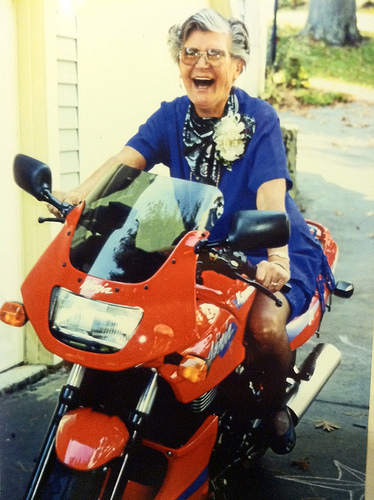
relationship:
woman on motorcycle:
[45, 9, 333, 455] [1, 153, 344, 498]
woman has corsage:
[45, 9, 333, 455] [212, 107, 248, 164]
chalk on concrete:
[275, 456, 362, 500] [3, 98, 373, 499]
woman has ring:
[45, 9, 333, 455] [269, 279, 279, 287]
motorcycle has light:
[1, 153, 344, 498] [49, 283, 144, 351]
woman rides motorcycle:
[45, 9, 333, 455] [1, 153, 344, 498]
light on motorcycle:
[49, 283, 144, 351] [1, 153, 344, 498]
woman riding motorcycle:
[45, 9, 333, 455] [1, 153, 344, 498]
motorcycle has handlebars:
[1, 153, 344, 498] [198, 240, 292, 308]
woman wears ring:
[45, 9, 333, 455] [269, 279, 279, 287]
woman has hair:
[45, 9, 333, 455] [167, 7, 250, 66]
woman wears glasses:
[45, 9, 333, 455] [177, 46, 233, 62]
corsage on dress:
[212, 107, 248, 164] [125, 87, 336, 337]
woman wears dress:
[45, 9, 333, 455] [125, 87, 336, 337]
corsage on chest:
[212, 107, 248, 164] [161, 101, 278, 246]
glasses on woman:
[177, 46, 233, 62] [45, 9, 333, 455]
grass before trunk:
[267, 21, 373, 105] [295, 1, 370, 47]